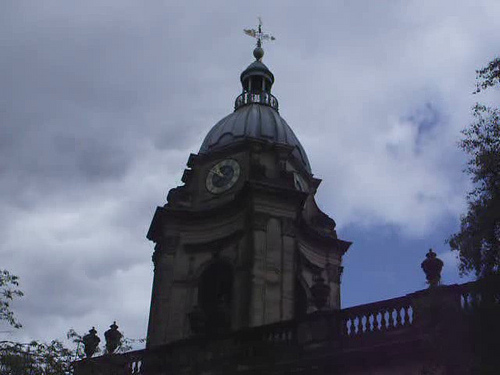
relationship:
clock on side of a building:
[204, 157, 241, 195] [145, 10, 359, 375]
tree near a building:
[0, 263, 95, 373] [145, 10, 359, 375]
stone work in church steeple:
[256, 230, 294, 328] [142, 24, 355, 350]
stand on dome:
[232, 88, 284, 108] [190, 6, 313, 158]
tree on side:
[437, 41, 498, 282] [452, 10, 499, 348]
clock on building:
[201, 152, 246, 197] [128, 12, 373, 344]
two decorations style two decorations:
[80, 320, 126, 357] [80, 320, 126, 357]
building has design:
[145, 10, 359, 375] [168, 157, 331, 311]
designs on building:
[186, 130, 315, 313] [132, 10, 359, 370]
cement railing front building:
[74, 280, 500, 375] [112, 8, 386, 364]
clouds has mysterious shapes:
[17, 55, 149, 195] [30, 61, 131, 201]